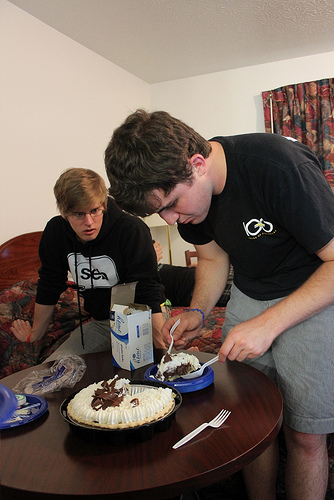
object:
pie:
[51, 376, 186, 445]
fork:
[171, 407, 233, 449]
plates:
[144, 351, 220, 396]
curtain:
[260, 77, 334, 190]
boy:
[41, 159, 129, 314]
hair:
[101, 107, 213, 220]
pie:
[150, 342, 218, 378]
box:
[106, 278, 154, 371]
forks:
[159, 310, 231, 390]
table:
[0, 321, 289, 498]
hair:
[52, 164, 108, 220]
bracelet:
[183, 308, 207, 319]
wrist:
[180, 303, 208, 324]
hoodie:
[34, 197, 166, 326]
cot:
[1, 228, 43, 287]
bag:
[11, 351, 86, 397]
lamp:
[130, 193, 185, 271]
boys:
[35, 110, 333, 499]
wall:
[0, 0, 155, 206]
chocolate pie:
[155, 349, 201, 383]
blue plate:
[142, 356, 213, 394]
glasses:
[70, 205, 101, 219]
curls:
[90, 380, 136, 412]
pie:
[59, 376, 183, 430]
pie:
[57, 371, 181, 427]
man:
[101, 98, 333, 495]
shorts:
[213, 295, 333, 437]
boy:
[9, 168, 172, 368]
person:
[9, 166, 178, 367]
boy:
[103, 100, 331, 499]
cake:
[69, 374, 177, 432]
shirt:
[178, 134, 334, 302]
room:
[0, 0, 330, 498]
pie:
[162, 341, 202, 384]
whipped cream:
[65, 371, 177, 426]